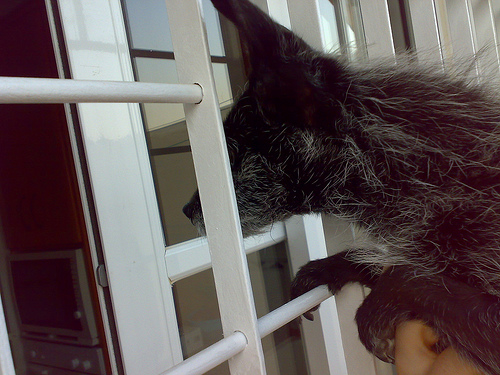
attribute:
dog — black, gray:
[155, 10, 499, 348]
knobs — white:
[9, 301, 98, 373]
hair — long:
[277, 54, 493, 270]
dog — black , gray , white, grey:
[177, 1, 499, 371]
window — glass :
[51, 0, 411, 373]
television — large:
[10, 247, 103, 344]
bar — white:
[4, 74, 202, 109]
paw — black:
[287, 257, 344, 323]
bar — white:
[244, 282, 348, 337]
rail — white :
[151, 263, 362, 372]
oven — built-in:
[5, 247, 108, 372]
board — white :
[166, 24, 299, 373]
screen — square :
[5, 258, 91, 331]